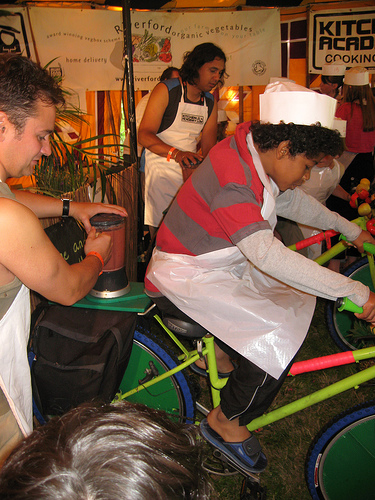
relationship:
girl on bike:
[146, 76, 374, 481] [92, 253, 375, 495]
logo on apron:
[180, 110, 205, 127] [144, 79, 207, 224]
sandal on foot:
[197, 420, 273, 496] [193, 397, 280, 484]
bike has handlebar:
[92, 253, 375, 495] [336, 299, 370, 323]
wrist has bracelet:
[77, 240, 117, 278] [86, 250, 108, 273]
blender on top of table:
[83, 213, 130, 296] [61, 281, 156, 320]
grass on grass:
[168, 356, 374, 492] [168, 356, 373, 500]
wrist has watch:
[77, 240, 117, 278] [59, 197, 78, 216]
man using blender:
[0, 56, 119, 440] [83, 213, 130, 296]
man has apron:
[0, 56, 119, 440] [1, 255, 35, 432]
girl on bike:
[146, 73, 354, 479] [92, 253, 375, 495]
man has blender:
[0, 56, 119, 440] [83, 213, 130, 296]